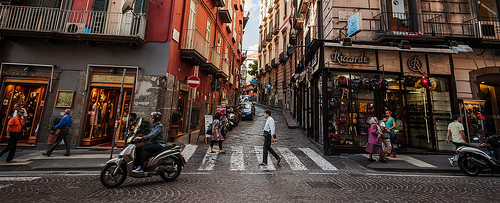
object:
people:
[257, 110, 283, 165]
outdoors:
[0, 0, 500, 203]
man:
[131, 111, 167, 173]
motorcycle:
[99, 136, 186, 188]